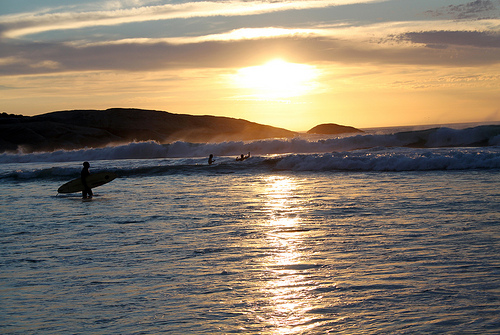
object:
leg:
[80, 182, 89, 199]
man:
[80, 161, 97, 203]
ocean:
[0, 122, 500, 335]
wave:
[2, 143, 500, 186]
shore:
[0, 127, 500, 177]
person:
[205, 153, 218, 167]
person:
[238, 153, 248, 163]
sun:
[233, 54, 326, 108]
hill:
[0, 108, 302, 147]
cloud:
[0, 0, 385, 34]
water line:
[358, 120, 483, 129]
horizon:
[259, 107, 483, 125]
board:
[52, 168, 124, 194]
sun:
[255, 168, 314, 333]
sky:
[1, 1, 500, 134]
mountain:
[304, 120, 371, 140]